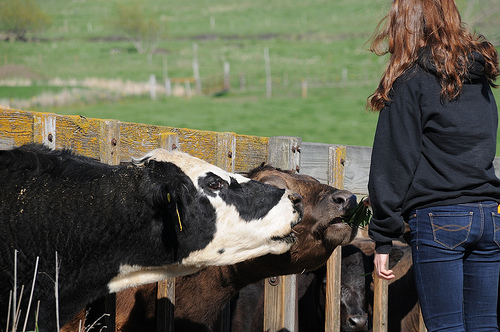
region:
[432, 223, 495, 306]
the jeans are blue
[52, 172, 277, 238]
the cow is black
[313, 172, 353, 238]
the cow is brown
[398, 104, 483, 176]
the top is blue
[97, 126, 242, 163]
the cows pen is made of wood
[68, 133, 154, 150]
the wood is yellow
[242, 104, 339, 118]
the grass is green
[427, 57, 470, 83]
the hair is brown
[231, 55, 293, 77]
the poles are made of wood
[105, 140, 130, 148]
the nails are on the wood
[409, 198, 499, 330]
the jeans are blue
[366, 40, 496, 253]
the sweatshirt is dark and long sleeved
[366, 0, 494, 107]
long brown hair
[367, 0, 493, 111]
long brown messy hair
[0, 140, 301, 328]
cow with black and white fur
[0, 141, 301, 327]
cow with fur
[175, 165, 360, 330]
brown cow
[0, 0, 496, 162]
grass is green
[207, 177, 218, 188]
brown eye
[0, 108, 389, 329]
the fence is wooden and painted yellow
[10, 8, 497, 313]
A woman and three cows.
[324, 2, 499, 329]
The woman is holding a plant in her right hand.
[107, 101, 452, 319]
The cows are trying to eat the plant.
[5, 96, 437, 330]
A wooden fence.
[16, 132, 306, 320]
The cow is black and white.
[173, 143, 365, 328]
The cow is dark brown.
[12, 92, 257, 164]
Remnants of yellow paint on the wood.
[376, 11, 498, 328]
The woman is wearing a hoodie and jeans.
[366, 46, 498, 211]
The hoodie is black.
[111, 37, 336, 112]
Posts from an old fence that is no longer there.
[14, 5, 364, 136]
the grass are green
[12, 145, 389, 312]
this animals are green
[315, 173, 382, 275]
the cow is eating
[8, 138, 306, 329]
the cow is black and white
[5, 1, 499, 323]
the photo is clear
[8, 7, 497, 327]
the photo was taken during the day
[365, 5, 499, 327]
the lady is wearing clothes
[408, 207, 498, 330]
the lady has blue jeans on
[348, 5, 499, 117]
the lady has brown hair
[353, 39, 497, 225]
the lady has a black hoodie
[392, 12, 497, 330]
woman with brown hair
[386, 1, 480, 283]
woman in black sweatshirt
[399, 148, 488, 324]
blue jeans on a woman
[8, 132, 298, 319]
black and white couw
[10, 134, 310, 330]
cow with fluffy fur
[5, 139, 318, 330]
two cows in a pen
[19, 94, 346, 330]
wooden fence around a pen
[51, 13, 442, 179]
grassy hill by a cow pen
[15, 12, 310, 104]
trees on a grassy pen